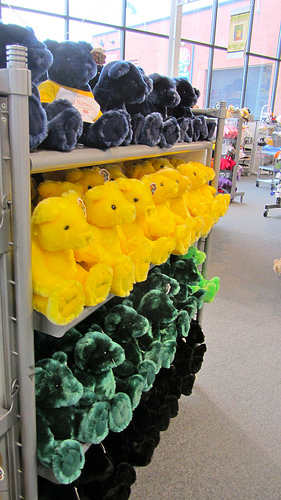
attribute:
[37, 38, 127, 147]
bear — navy, black, small, blue, stuffed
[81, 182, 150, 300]
teddy — bright, yellow, facing, row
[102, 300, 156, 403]
stuffed animal — green, row, light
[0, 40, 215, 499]
shelf — gray, edged, grey, metal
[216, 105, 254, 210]
rack — pink, cloths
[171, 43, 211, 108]
window — glass, pane, transparent, storefront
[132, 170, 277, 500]
floor — beige, carpet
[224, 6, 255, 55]
banner — white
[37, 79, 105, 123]
shirt — yellow, white